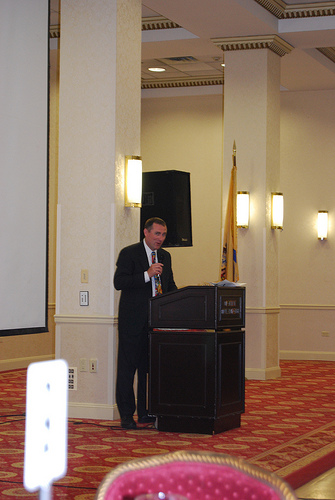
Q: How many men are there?
A: One.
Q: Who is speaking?
A: Man.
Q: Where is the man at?
A: Conference room.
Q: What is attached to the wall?
A: Light fixtures.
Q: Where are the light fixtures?
A: Wall.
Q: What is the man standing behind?
A: Podium.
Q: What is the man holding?
A: Microphone.